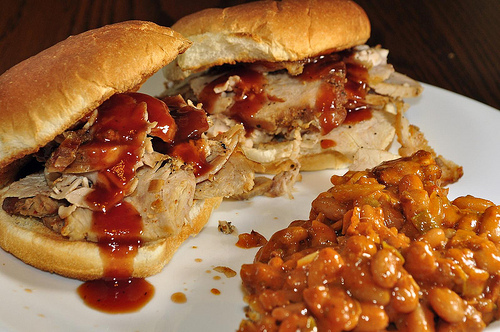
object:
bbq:
[32, 67, 219, 317]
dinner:
[4, 2, 497, 329]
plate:
[1, 70, 499, 328]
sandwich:
[165, 11, 413, 170]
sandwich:
[0, 19, 227, 284]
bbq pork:
[229, 72, 351, 135]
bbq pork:
[51, 100, 150, 211]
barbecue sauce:
[76, 135, 153, 313]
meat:
[67, 50, 390, 225]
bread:
[0, 0, 225, 283]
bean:
[366, 247, 408, 290]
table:
[5, 1, 500, 332]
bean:
[367, 241, 397, 281]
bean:
[398, 172, 432, 214]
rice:
[295, 194, 313, 211]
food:
[0, 17, 500, 332]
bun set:
[175, 5, 433, 186]